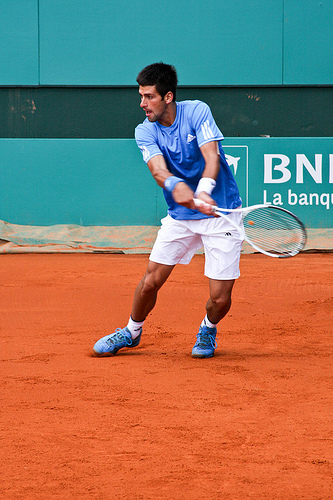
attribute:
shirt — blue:
[134, 93, 245, 223]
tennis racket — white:
[188, 194, 307, 262]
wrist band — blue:
[151, 165, 186, 206]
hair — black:
[135, 62, 177, 102]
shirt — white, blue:
[133, 99, 241, 218]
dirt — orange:
[0, 252, 331, 498]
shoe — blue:
[89, 325, 142, 356]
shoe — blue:
[189, 323, 218, 356]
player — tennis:
[61, 40, 268, 371]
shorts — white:
[147, 203, 244, 278]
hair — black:
[135, 56, 182, 107]